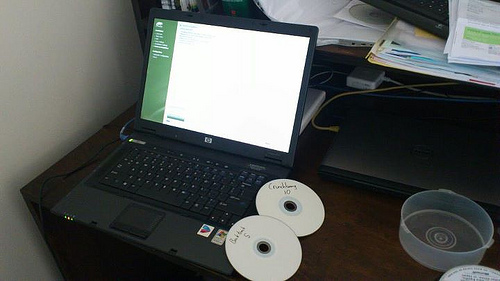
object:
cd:
[254, 179, 324, 238]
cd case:
[399, 188, 496, 271]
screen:
[135, 18, 312, 154]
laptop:
[50, 8, 317, 277]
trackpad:
[107, 203, 164, 239]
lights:
[128, 138, 133, 141]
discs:
[224, 215, 301, 279]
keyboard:
[84, 143, 275, 231]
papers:
[375, 41, 499, 87]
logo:
[204, 137, 212, 144]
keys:
[142, 172, 157, 181]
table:
[20, 86, 500, 281]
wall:
[0, 0, 151, 281]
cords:
[311, 83, 453, 127]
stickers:
[196, 223, 215, 238]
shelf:
[314, 41, 500, 87]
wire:
[319, 76, 331, 83]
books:
[451, 7, 499, 60]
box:
[345, 69, 387, 90]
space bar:
[136, 188, 185, 207]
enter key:
[225, 196, 252, 209]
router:
[300, 87, 327, 136]